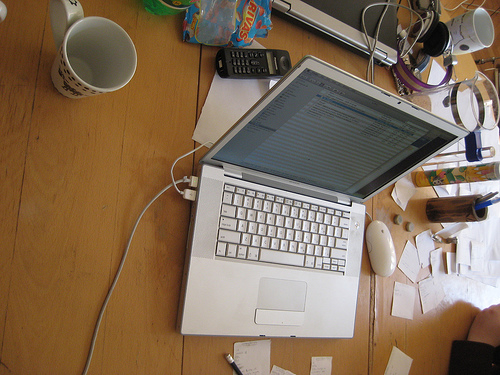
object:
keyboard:
[214, 184, 353, 282]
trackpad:
[247, 274, 314, 312]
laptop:
[136, 49, 471, 349]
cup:
[444, 6, 494, 56]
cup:
[50, 0, 138, 101]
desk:
[35, 27, 462, 357]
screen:
[198, 56, 478, 197]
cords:
[86, 139, 201, 372]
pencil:
[215, 350, 251, 372]